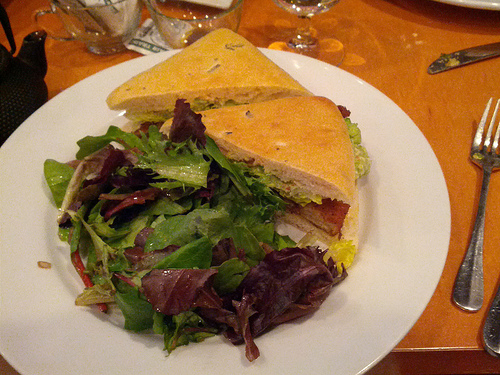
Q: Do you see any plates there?
A: Yes, there is a plate.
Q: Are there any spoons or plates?
A: Yes, there is a plate.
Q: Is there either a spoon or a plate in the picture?
A: Yes, there is a plate.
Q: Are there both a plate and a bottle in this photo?
A: No, there is a plate but no bottles.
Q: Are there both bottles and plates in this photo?
A: No, there is a plate but no bottles.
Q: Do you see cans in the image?
A: No, there are no cans.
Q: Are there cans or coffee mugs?
A: No, there are no cans or coffee mugs.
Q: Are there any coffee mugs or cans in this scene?
A: No, there are no cans or coffee mugs.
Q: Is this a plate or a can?
A: This is a plate.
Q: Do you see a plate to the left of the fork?
A: Yes, there is a plate to the left of the fork.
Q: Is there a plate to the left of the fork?
A: Yes, there is a plate to the left of the fork.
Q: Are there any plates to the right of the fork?
A: No, the plate is to the left of the fork.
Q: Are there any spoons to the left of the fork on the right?
A: No, there is a plate to the left of the fork.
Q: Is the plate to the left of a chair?
A: No, the plate is to the left of the fork.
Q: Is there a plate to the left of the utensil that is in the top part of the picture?
A: Yes, there is a plate to the left of the knife.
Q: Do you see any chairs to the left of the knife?
A: No, there is a plate to the left of the knife.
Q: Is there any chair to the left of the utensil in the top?
A: No, there is a plate to the left of the knife.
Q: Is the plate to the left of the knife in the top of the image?
A: Yes, the plate is to the left of the knife.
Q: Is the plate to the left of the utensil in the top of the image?
A: Yes, the plate is to the left of the knife.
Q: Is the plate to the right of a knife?
A: No, the plate is to the left of a knife.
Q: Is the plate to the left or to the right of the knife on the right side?
A: The plate is to the left of the knife.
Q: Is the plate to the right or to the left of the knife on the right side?
A: The plate is to the left of the knife.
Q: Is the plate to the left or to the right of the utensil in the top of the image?
A: The plate is to the left of the knife.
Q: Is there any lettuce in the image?
A: Yes, there is lettuce.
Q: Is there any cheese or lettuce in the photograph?
A: Yes, there is lettuce.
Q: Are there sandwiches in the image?
A: Yes, there is a sandwich.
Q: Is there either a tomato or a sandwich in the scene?
A: Yes, there is a sandwich.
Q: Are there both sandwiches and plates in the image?
A: Yes, there are both a sandwich and a plate.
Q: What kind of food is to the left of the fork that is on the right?
A: The food is a sandwich.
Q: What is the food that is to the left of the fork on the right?
A: The food is a sandwich.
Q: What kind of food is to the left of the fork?
A: The food is a sandwich.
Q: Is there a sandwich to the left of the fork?
A: Yes, there is a sandwich to the left of the fork.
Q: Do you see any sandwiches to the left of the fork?
A: Yes, there is a sandwich to the left of the fork.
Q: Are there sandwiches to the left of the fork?
A: Yes, there is a sandwich to the left of the fork.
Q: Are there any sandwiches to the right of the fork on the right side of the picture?
A: No, the sandwich is to the left of the fork.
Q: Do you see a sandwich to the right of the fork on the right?
A: No, the sandwich is to the left of the fork.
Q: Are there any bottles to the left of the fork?
A: No, there is a sandwich to the left of the fork.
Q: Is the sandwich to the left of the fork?
A: Yes, the sandwich is to the left of the fork.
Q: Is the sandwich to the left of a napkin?
A: No, the sandwich is to the left of the fork.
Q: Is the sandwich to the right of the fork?
A: No, the sandwich is to the left of the fork.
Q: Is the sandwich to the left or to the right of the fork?
A: The sandwich is to the left of the fork.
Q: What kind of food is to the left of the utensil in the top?
A: The food is a sandwich.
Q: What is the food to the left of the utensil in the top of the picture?
A: The food is a sandwich.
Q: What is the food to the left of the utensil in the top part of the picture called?
A: The food is a sandwich.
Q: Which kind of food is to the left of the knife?
A: The food is a sandwich.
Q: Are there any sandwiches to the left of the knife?
A: Yes, there is a sandwich to the left of the knife.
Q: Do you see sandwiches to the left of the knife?
A: Yes, there is a sandwich to the left of the knife.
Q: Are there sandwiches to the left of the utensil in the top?
A: Yes, there is a sandwich to the left of the knife.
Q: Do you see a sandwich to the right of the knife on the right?
A: No, the sandwich is to the left of the knife.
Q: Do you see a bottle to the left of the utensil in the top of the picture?
A: No, there is a sandwich to the left of the knife.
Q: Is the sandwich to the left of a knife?
A: Yes, the sandwich is to the left of a knife.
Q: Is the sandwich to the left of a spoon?
A: No, the sandwich is to the left of a knife.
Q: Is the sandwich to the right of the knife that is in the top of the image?
A: No, the sandwich is to the left of the knife.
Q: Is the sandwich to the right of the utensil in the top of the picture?
A: No, the sandwich is to the left of the knife.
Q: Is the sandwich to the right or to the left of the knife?
A: The sandwich is to the left of the knife.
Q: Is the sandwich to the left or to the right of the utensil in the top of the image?
A: The sandwich is to the left of the knife.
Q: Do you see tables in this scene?
A: Yes, there is a table.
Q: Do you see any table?
A: Yes, there is a table.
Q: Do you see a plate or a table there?
A: Yes, there is a table.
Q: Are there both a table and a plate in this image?
A: Yes, there are both a table and a plate.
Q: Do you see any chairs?
A: No, there are no chairs.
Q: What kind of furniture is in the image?
A: The furniture is a table.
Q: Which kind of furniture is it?
A: The piece of furniture is a table.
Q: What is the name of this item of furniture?
A: This is a table.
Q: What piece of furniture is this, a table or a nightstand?
A: This is a table.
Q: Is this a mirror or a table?
A: This is a table.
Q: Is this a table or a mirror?
A: This is a table.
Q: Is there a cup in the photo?
A: Yes, there is a cup.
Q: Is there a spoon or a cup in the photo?
A: Yes, there is a cup.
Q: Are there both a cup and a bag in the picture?
A: No, there is a cup but no bags.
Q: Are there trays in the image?
A: No, there are no trays.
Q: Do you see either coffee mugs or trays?
A: No, there are no trays or coffee mugs.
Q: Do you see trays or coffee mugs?
A: No, there are no trays or coffee mugs.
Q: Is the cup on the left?
A: Yes, the cup is on the left of the image.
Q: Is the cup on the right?
A: No, the cup is on the left of the image.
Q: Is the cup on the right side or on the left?
A: The cup is on the left of the image.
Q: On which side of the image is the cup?
A: The cup is on the left of the image.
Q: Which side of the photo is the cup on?
A: The cup is on the left of the image.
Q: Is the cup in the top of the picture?
A: Yes, the cup is in the top of the image.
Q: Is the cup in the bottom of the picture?
A: No, the cup is in the top of the image.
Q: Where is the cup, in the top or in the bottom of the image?
A: The cup is in the top of the image.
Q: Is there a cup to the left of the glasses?
A: Yes, there is a cup to the left of the glasses.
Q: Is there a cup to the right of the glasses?
A: No, the cup is to the left of the glasses.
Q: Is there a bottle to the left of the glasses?
A: No, there is a cup to the left of the glasses.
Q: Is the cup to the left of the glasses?
A: Yes, the cup is to the left of the glasses.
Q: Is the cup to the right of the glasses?
A: No, the cup is to the left of the glasses.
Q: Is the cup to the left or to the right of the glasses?
A: The cup is to the left of the glasses.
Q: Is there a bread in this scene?
A: Yes, there is a bread.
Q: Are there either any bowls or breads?
A: Yes, there is a bread.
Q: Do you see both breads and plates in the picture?
A: Yes, there are both a bread and a plate.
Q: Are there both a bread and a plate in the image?
A: Yes, there are both a bread and a plate.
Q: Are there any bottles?
A: No, there are no bottles.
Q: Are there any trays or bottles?
A: No, there are no bottles or trays.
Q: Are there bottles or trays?
A: No, there are no bottles or trays.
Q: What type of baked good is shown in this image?
A: The baked good is a bread.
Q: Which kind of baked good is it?
A: The food is a bread.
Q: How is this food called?
A: This is a bread.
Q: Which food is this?
A: This is a bread.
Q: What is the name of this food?
A: This is a bread.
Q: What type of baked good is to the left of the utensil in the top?
A: The food is a bread.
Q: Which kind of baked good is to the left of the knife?
A: The food is a bread.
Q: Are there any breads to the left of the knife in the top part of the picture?
A: Yes, there is a bread to the left of the knife.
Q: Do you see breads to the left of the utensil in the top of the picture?
A: Yes, there is a bread to the left of the knife.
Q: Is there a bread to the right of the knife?
A: No, the bread is to the left of the knife.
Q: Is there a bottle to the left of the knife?
A: No, there is a bread to the left of the knife.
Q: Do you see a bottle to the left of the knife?
A: No, there is a bread to the left of the knife.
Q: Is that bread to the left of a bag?
A: No, the bread is to the left of the knife.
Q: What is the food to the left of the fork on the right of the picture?
A: The food is a bread.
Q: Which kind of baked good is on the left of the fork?
A: The food is a bread.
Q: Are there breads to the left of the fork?
A: Yes, there is a bread to the left of the fork.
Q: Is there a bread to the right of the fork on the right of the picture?
A: No, the bread is to the left of the fork.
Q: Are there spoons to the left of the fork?
A: No, there is a bread to the left of the fork.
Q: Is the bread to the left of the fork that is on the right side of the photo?
A: Yes, the bread is to the left of the fork.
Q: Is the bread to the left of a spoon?
A: No, the bread is to the left of the fork.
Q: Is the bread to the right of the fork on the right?
A: No, the bread is to the left of the fork.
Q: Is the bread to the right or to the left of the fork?
A: The bread is to the left of the fork.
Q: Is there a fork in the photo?
A: Yes, there is a fork.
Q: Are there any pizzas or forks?
A: Yes, there is a fork.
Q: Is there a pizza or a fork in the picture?
A: Yes, there is a fork.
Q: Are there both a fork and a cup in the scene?
A: Yes, there are both a fork and a cup.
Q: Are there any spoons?
A: No, there are no spoons.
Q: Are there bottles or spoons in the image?
A: No, there are no spoons or bottles.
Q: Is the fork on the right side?
A: Yes, the fork is on the right of the image.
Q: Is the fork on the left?
A: No, the fork is on the right of the image.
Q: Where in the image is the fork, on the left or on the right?
A: The fork is on the right of the image.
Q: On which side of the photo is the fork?
A: The fork is on the right of the image.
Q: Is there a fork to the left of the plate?
A: No, the fork is to the right of the plate.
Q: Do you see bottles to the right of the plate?
A: No, there is a fork to the right of the plate.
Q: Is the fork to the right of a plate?
A: Yes, the fork is to the right of a plate.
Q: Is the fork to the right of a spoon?
A: No, the fork is to the right of a plate.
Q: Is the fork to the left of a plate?
A: No, the fork is to the right of a plate.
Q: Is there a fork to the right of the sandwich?
A: Yes, there is a fork to the right of the sandwich.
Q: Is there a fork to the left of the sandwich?
A: No, the fork is to the right of the sandwich.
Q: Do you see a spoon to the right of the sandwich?
A: No, there is a fork to the right of the sandwich.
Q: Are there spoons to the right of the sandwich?
A: No, there is a fork to the right of the sandwich.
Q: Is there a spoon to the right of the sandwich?
A: No, there is a fork to the right of the sandwich.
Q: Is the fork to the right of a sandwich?
A: Yes, the fork is to the right of a sandwich.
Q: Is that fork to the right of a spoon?
A: No, the fork is to the right of a sandwich.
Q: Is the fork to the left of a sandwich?
A: No, the fork is to the right of a sandwich.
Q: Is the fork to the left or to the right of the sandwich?
A: The fork is to the right of the sandwich.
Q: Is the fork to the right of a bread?
A: Yes, the fork is to the right of a bread.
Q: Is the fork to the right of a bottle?
A: No, the fork is to the right of a bread.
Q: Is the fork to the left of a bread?
A: No, the fork is to the right of a bread.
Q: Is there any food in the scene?
A: Yes, there is food.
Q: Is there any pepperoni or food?
A: Yes, there is food.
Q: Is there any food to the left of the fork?
A: Yes, there is food to the left of the fork.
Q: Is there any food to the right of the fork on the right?
A: No, the food is to the left of the fork.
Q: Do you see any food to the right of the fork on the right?
A: No, the food is to the left of the fork.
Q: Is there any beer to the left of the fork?
A: No, there is food to the left of the fork.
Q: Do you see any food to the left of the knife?
A: Yes, there is food to the left of the knife.